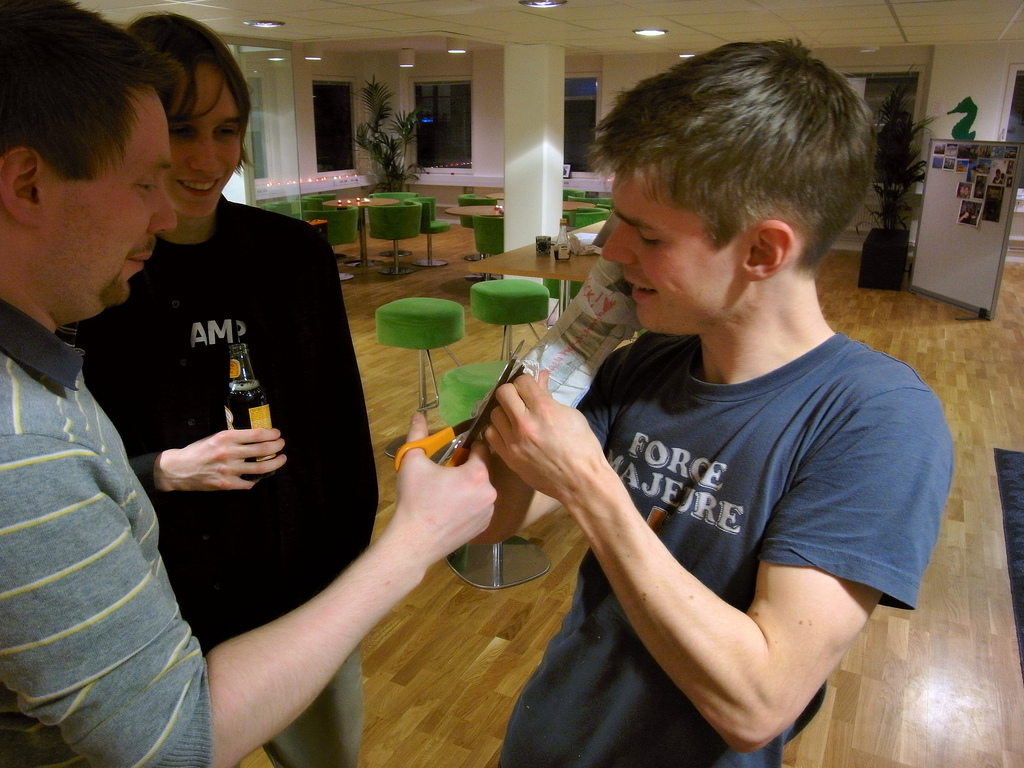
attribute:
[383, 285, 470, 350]
seat — green, stool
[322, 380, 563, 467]
scissors — orange, metal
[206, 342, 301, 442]
bottle — glass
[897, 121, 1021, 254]
pictures — display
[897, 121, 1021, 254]
board — display, white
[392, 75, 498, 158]
window — dark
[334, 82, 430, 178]
plant — green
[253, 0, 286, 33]
light — recessed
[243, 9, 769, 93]
ceiling — lit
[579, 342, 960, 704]
shirt — grey, t-shirt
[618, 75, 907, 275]
haircut — short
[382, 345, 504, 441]
wall — pink, green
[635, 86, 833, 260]
head — brown hair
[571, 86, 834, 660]
boy — standing, smilling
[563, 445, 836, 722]
arm — broken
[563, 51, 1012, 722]
man — boy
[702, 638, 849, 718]
elbow — bent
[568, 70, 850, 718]
man — boy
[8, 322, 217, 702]
shirt — lines, green, yellow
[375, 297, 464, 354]
cushion — green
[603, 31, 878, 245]
hair — brown